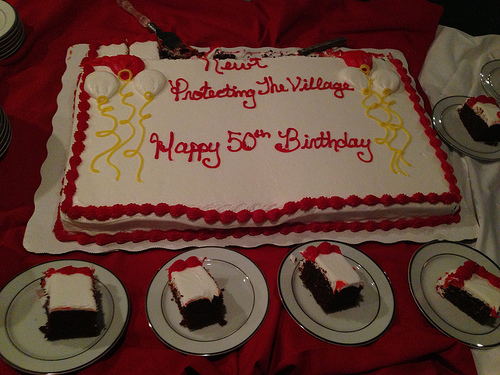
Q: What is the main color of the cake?
A: White.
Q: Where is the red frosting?
A: Around the cake.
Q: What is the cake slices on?
A: A plate.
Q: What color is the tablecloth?
A: Red.